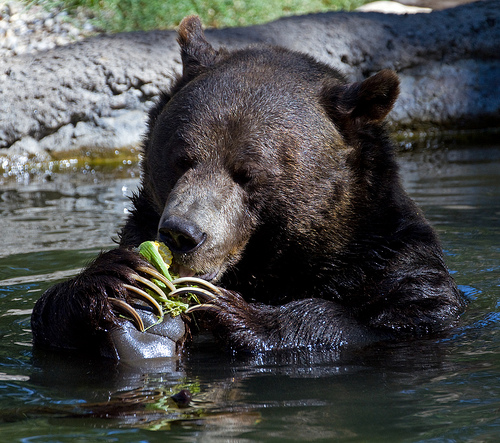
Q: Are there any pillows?
A: No, there are no pillows.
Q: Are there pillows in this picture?
A: No, there are no pillows.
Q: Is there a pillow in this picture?
A: No, there are no pillows.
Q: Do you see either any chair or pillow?
A: No, there are no pillows or chairs.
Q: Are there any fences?
A: No, there are no fences.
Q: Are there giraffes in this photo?
A: No, there are no giraffes.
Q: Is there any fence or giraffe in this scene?
A: No, there are no giraffes or fences.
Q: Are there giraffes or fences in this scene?
A: No, there are no giraffes or fences.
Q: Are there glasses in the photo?
A: No, there are no glasses.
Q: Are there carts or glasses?
A: No, there are no glasses or carts.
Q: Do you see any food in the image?
A: Yes, there is food.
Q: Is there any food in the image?
A: Yes, there is food.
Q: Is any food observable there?
A: Yes, there is food.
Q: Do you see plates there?
A: No, there are no plates.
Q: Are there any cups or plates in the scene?
A: No, there are no plates or cups.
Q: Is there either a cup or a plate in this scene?
A: No, there are no plates or cups.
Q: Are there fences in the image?
A: No, there are no fences.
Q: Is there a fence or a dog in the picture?
A: No, there are no fences or dogs.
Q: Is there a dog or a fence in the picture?
A: No, there are no fences or dogs.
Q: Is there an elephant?
A: No, there are no elephants.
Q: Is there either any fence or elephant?
A: No, there are no elephants or fences.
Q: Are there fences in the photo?
A: No, there are no fences.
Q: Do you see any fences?
A: No, there are no fences.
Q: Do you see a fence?
A: No, there are no fences.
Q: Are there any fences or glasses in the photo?
A: No, there are no fences or glasses.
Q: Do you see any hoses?
A: No, there are no hoses.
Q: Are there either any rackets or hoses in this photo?
A: No, there are no hoses or rackets.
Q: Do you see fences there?
A: No, there are no fences.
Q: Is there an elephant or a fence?
A: No, there are no fences or elephants.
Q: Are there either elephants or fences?
A: No, there are no fences or elephants.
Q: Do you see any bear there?
A: Yes, there is a bear.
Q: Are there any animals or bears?
A: Yes, there is a bear.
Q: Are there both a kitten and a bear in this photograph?
A: No, there is a bear but no kittens.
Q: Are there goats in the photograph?
A: No, there are no goats.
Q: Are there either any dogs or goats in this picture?
A: No, there are no goats or dogs.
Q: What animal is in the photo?
A: The animal is a bear.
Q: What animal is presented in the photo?
A: The animal is a bear.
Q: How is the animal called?
A: The animal is a bear.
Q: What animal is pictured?
A: The animal is a bear.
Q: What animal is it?
A: The animal is a bear.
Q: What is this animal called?
A: This is a bear.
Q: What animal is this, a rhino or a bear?
A: This is a bear.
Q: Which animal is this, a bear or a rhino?
A: This is a bear.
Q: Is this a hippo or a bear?
A: This is a bear.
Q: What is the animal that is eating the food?
A: The animal is a bear.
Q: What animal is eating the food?
A: The animal is a bear.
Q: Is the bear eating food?
A: Yes, the bear is eating food.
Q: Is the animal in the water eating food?
A: Yes, the bear is eating food.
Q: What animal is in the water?
A: The bear is in the water.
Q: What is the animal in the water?
A: The animal is a bear.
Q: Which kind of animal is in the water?
A: The animal is a bear.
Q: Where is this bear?
A: The bear is in the water.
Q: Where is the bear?
A: The bear is in the water.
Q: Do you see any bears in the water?
A: Yes, there is a bear in the water.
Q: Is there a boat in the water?
A: No, there is a bear in the water.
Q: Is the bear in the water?
A: Yes, the bear is in the water.